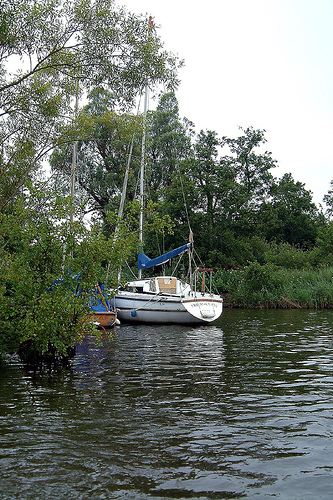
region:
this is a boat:
[60, 3, 250, 342]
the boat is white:
[99, 247, 233, 349]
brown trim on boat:
[121, 285, 221, 318]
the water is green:
[114, 329, 286, 474]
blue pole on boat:
[133, 233, 215, 278]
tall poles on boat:
[107, 5, 226, 307]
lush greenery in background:
[183, 127, 327, 355]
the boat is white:
[115, 253, 225, 332]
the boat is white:
[97, 265, 233, 338]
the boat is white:
[105, 266, 226, 332]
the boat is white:
[101, 261, 228, 326]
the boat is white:
[96, 266, 229, 343]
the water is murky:
[121, 347, 262, 450]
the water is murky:
[134, 343, 235, 432]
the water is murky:
[163, 358, 274, 421]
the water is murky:
[117, 319, 211, 418]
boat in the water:
[94, 255, 241, 345]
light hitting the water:
[190, 361, 307, 468]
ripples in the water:
[115, 346, 243, 430]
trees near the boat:
[171, 161, 269, 217]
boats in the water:
[44, 230, 254, 349]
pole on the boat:
[111, 127, 174, 244]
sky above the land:
[207, 34, 290, 86]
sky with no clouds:
[204, 25, 301, 80]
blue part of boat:
[104, 235, 195, 288]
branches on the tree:
[176, 133, 261, 197]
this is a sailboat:
[95, 24, 261, 376]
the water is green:
[114, 333, 296, 492]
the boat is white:
[91, 235, 248, 365]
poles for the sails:
[92, 51, 191, 332]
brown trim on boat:
[113, 281, 216, 323]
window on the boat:
[117, 279, 145, 297]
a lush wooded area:
[193, 160, 331, 310]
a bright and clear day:
[2, 4, 331, 473]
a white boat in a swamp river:
[94, 11, 229, 330]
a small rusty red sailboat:
[42, 64, 123, 332]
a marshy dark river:
[8, 293, 324, 493]